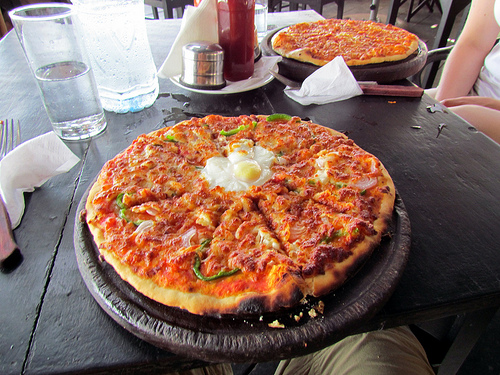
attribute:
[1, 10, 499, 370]
wood — brown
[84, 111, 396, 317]
pizza — tasty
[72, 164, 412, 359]
plate — wooden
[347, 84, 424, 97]
handle — wooden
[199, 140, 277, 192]
egg — sunnyside up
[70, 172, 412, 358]
tray — brown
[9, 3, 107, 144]
glass — clear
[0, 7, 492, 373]
table — brown, dark, wooden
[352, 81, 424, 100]
handle — brown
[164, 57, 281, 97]
plate — white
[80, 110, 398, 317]
pizza pie — large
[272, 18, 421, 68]
pizza pie — large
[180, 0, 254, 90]
bottles — red, silver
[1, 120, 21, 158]
fork — silver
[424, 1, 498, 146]
person — sitting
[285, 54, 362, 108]
napkin — used, white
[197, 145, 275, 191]
egg — fried 